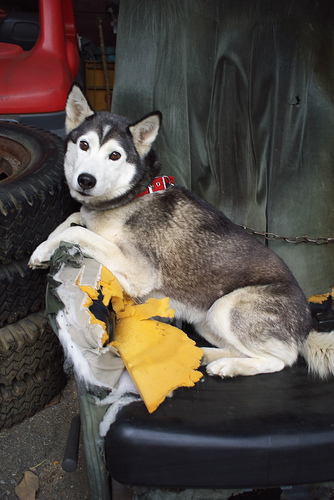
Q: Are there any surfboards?
A: No, there are no surfboards.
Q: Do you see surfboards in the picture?
A: No, there are no surfboards.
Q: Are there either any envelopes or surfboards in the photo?
A: No, there are no surfboards or envelopes.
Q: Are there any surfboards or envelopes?
A: No, there are no surfboards or envelopes.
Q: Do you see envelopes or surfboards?
A: No, there are no surfboards or envelopes.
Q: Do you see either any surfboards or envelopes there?
A: No, there are no surfboards or envelopes.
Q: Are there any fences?
A: No, there are no fences.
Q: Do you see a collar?
A: Yes, there is a collar.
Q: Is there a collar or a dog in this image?
A: Yes, there is a collar.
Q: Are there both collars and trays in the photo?
A: No, there is a collar but no trays.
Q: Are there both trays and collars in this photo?
A: No, there is a collar but no trays.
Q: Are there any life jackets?
A: No, there are no life jackets.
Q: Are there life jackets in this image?
A: No, there are no life jackets.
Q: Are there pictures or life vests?
A: No, there are no life vests or pictures.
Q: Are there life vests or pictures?
A: No, there are no life vests or pictures.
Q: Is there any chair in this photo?
A: Yes, there is a chair.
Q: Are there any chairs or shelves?
A: Yes, there is a chair.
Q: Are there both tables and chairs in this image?
A: No, there is a chair but no tables.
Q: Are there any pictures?
A: No, there are no pictures.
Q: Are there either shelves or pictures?
A: No, there are no pictures or shelves.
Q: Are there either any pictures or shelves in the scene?
A: No, there are no pictures or shelves.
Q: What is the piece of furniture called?
A: The piece of furniture is a chair.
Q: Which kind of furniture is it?
A: The piece of furniture is a chair.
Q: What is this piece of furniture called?
A: This is a chair.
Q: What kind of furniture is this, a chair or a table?
A: This is a chair.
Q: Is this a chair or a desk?
A: This is a chair.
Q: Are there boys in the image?
A: No, there are no boys.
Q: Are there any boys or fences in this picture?
A: No, there are no boys or fences.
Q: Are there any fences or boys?
A: No, there are no boys or fences.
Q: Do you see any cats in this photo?
A: No, there are no cats.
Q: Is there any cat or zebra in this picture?
A: No, there are no cats or zebras.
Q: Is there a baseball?
A: No, there are no baseballs.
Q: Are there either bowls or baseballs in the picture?
A: No, there are no baseballs or bowls.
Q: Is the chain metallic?
A: Yes, the chain is metallic.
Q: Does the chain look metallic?
A: Yes, the chain is metallic.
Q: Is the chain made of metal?
A: Yes, the chain is made of metal.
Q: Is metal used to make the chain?
A: Yes, the chain is made of metal.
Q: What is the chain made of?
A: The chain is made of metal.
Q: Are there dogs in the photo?
A: Yes, there is a dog.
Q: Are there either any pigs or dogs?
A: Yes, there is a dog.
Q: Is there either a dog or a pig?
A: Yes, there is a dog.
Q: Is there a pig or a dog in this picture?
A: Yes, there is a dog.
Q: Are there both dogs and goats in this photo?
A: No, there is a dog but no goats.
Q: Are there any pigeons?
A: No, there are no pigeons.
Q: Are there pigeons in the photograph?
A: No, there are no pigeons.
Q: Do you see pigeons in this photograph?
A: No, there are no pigeons.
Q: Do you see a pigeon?
A: No, there are no pigeons.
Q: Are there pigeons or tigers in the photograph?
A: No, there are no pigeons or tigers.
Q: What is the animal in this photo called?
A: The animal is a dog.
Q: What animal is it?
A: The animal is a dog.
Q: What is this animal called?
A: This is a dog.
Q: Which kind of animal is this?
A: This is a dog.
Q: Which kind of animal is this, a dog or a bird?
A: This is a dog.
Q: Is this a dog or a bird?
A: This is a dog.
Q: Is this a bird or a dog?
A: This is a dog.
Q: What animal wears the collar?
A: The dog wears a collar.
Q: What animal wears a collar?
A: The animal is a dog.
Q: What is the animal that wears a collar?
A: The animal is a dog.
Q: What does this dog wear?
A: The dog wears a collar.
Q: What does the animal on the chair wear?
A: The dog wears a collar.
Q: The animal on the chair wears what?
A: The dog wears a collar.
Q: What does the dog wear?
A: The dog wears a collar.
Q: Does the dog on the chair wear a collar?
A: Yes, the dog wears a collar.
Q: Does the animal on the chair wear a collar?
A: Yes, the dog wears a collar.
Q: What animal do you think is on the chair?
A: The dog is on the chair.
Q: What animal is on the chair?
A: The dog is on the chair.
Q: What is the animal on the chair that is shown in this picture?
A: The animal is a dog.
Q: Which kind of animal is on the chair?
A: The animal is a dog.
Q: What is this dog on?
A: The dog is on the chair.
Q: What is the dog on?
A: The dog is on the chair.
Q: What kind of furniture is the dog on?
A: The dog is on the chair.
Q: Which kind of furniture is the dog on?
A: The dog is on the chair.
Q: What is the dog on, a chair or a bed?
A: The dog is on a chair.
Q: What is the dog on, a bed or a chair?
A: The dog is on a chair.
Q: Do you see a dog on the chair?
A: Yes, there is a dog on the chair.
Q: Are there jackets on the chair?
A: No, there is a dog on the chair.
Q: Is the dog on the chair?
A: Yes, the dog is on the chair.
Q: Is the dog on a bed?
A: No, the dog is on the chair.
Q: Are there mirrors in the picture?
A: No, there are no mirrors.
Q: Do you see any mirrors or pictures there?
A: No, there are no mirrors or pictures.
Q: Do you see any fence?
A: No, there are no fences.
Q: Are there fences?
A: No, there are no fences.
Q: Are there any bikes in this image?
A: No, there are no bikes.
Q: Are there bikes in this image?
A: No, there are no bikes.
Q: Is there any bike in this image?
A: No, there are no bikes.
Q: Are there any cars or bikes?
A: No, there are no bikes or cars.